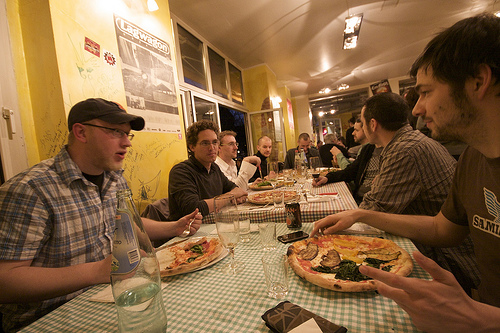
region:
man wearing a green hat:
[59, 98, 149, 144]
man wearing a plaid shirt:
[6, 143, 146, 275]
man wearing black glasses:
[77, 115, 144, 149]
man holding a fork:
[174, 202, 202, 242]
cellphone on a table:
[276, 224, 311, 242]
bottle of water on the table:
[102, 191, 169, 331]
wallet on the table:
[260, 293, 350, 331]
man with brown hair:
[184, 120, 227, 165]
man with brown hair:
[417, 11, 489, 147]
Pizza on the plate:
[291, 218, 421, 302]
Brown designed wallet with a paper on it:
[257, 302, 352, 332]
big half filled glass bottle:
[105, 188, 158, 330]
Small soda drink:
[282, 199, 305, 229]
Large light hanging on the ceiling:
[337, 14, 366, 57]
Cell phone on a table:
[276, 224, 308, 244]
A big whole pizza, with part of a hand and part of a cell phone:
[286, 226, 431, 298]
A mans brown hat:
[64, 90, 148, 130]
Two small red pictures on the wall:
[82, 31, 119, 73]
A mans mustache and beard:
[420, 77, 485, 146]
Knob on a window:
[0, 101, 25, 152]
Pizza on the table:
[289, 229, 416, 296]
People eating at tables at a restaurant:
[2, 25, 498, 321]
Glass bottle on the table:
[108, 184, 169, 331]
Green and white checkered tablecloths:
[18, 219, 419, 331]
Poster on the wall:
[112, 15, 181, 140]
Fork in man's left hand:
[178, 205, 203, 241]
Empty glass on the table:
[258, 247, 288, 300]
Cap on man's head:
[65, 98, 145, 128]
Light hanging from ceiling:
[342, 4, 365, 50]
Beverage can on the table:
[283, 200, 303, 232]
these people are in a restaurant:
[20, 17, 497, 320]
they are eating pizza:
[126, 220, 418, 302]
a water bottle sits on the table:
[103, 185, 175, 330]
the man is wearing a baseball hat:
[65, 95, 146, 139]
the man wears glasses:
[82, 123, 137, 145]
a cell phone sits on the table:
[278, 222, 313, 244]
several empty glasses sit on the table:
[210, 189, 292, 300]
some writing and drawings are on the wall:
[41, 78, 181, 215]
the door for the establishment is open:
[218, 106, 284, 167]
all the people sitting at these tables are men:
[17, 15, 496, 316]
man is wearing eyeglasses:
[54, 83, 156, 210]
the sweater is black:
[161, 157, 246, 231]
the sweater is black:
[158, 143, 268, 258]